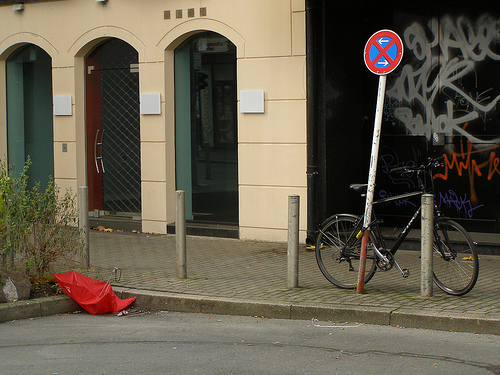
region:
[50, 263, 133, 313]
Broken red umbrella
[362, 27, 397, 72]
Red blue and white Traffic sign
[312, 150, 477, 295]
Black Bicycle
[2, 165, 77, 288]
Small sparse bushes.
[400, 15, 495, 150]
White graffiti on wall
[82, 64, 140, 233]
Large glass door with metal handle.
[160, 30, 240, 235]
Large arched glass window.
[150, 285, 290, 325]
Section of concrete curb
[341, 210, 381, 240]
Bike lock attached to sign pole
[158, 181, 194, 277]
Steel bollard on sidewalk.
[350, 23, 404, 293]
a street sign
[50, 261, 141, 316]
a red umbrella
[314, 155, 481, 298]
a black bicycle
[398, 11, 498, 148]
white graffiti on a wall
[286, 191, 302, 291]
a concrete post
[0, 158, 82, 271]
a green bush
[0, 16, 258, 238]
three archways on a building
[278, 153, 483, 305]
a bicycle by concrete posts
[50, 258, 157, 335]
a red umbrella on the ground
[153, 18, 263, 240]
an archway with a window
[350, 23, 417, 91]
red and blue sign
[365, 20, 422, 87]
sign on pole is circular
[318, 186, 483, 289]
bike is under sign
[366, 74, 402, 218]
pole with sign is white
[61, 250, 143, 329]
red umbrella on ground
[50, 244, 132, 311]
red umbrella is overturned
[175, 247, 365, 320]
grey brick sidewalk near bike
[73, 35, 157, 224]
arched doorway on building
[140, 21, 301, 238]
building has light tan walls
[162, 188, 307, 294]
metal poles near bike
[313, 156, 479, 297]
parked black bicycle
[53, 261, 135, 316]
broken red umbrella on the ground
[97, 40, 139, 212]
silver mesh in the doorway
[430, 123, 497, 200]
orange graffiti on black wall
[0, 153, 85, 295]
short plants with green leaves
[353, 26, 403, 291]
tall pole with circular sign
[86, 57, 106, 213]
red door with silver handle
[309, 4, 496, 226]
black wall with graffiti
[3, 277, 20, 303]
white piece of garbage near plants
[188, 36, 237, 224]
open dark doorway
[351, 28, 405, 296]
A red and blue sign on a pole.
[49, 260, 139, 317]
A red umbrella opened on the ground.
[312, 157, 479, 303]
A black framed bicycle.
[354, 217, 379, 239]
A yellow and black bicycle lock.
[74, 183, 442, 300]
Short silver poles coming up from the sidewalk.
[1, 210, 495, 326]
A grey bricked sidewalk.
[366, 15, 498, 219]
Graffiti on the side of a building.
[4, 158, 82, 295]
A small shrub.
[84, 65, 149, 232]
A front door on a building.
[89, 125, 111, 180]
A long silver door handle on a door.